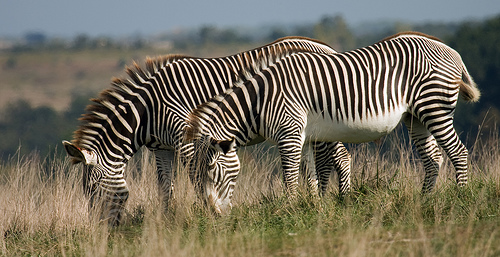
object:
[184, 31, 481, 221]
zebra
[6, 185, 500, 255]
field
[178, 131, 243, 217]
head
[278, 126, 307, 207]
leg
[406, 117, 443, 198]
leg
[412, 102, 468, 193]
leg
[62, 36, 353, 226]
zebra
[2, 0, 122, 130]
landscape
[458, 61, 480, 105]
tail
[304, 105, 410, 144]
underside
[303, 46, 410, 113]
stripes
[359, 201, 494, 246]
grass